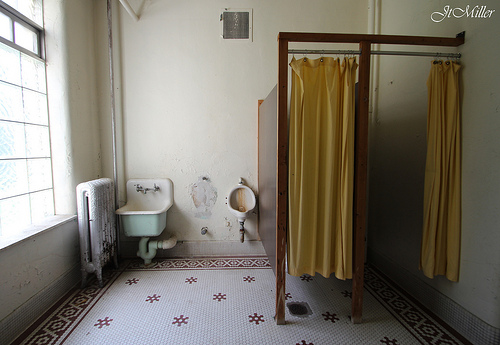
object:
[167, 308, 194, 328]
design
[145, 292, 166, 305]
design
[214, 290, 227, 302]
design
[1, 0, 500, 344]
bathroom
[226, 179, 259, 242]
urinal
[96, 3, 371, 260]
wall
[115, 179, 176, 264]
sink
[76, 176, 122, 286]
radiator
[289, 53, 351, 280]
curtain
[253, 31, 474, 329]
stall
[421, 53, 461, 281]
curtain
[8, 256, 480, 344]
tile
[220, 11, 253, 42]
vent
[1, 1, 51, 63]
window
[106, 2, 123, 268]
pole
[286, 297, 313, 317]
drain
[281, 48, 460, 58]
rod